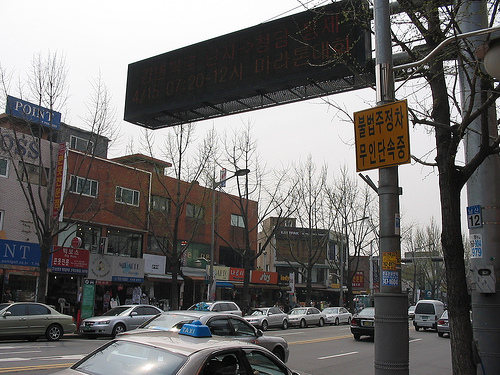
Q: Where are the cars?
A: On the street.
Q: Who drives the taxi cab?
A: Taxi Driver.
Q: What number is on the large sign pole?
A: 12.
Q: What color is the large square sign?
A: Yellow.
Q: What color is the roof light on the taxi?
A: Blue.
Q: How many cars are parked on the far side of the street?
A: Six.